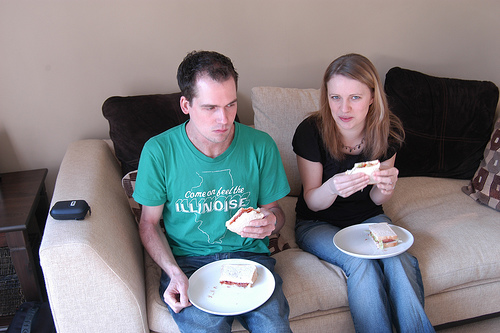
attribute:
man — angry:
[197, 88, 233, 147]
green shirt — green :
[155, 132, 288, 233]